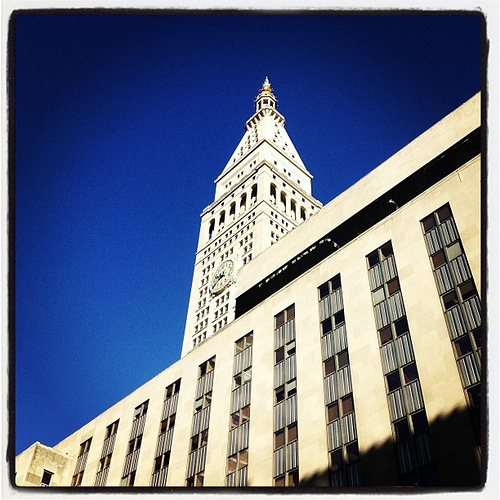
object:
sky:
[19, 32, 201, 211]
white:
[17, 71, 487, 489]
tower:
[179, 72, 339, 366]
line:
[261, 297, 314, 484]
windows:
[312, 261, 359, 492]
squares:
[317, 292, 349, 319]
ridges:
[317, 326, 352, 363]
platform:
[234, 89, 486, 324]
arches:
[191, 154, 331, 273]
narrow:
[208, 56, 322, 291]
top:
[231, 71, 306, 163]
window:
[270, 300, 303, 428]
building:
[316, 276, 353, 404]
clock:
[209, 258, 236, 297]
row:
[419, 199, 479, 428]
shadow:
[303, 388, 479, 487]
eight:
[264, 270, 360, 452]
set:
[348, 193, 493, 390]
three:
[181, 349, 228, 481]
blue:
[31, 28, 453, 67]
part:
[18, 394, 87, 493]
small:
[184, 228, 262, 345]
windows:
[174, 163, 262, 345]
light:
[229, 455, 248, 468]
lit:
[231, 331, 260, 388]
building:
[16, 74, 482, 487]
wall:
[309, 297, 439, 465]